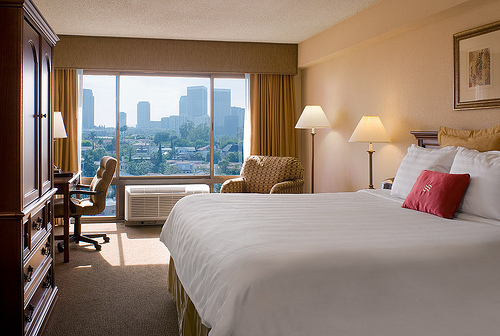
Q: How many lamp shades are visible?
A: Three.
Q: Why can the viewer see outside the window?
A: The curtains are open.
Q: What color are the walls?
A: Tan.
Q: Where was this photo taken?
A: A hotel room.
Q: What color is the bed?
A: White.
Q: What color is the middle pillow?
A: Red.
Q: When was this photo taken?
A: Inside, during the daytime.